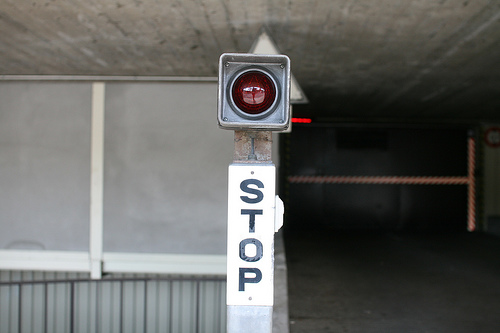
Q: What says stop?
A: The sign.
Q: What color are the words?
A: Black.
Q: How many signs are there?
A: One.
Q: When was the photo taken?
A: Day time.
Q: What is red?
A: The light.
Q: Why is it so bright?
A: Sunny.